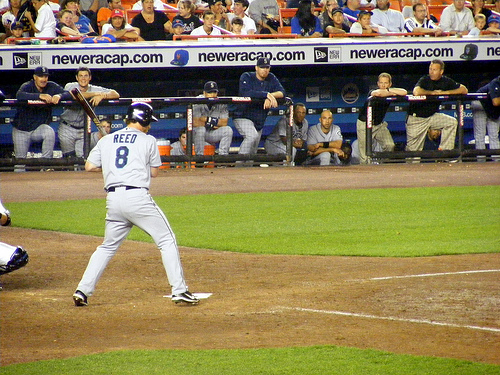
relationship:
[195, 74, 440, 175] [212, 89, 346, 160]
players leaning on fence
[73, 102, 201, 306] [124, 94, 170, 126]
batter wearing helmet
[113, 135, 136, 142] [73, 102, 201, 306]
name on batter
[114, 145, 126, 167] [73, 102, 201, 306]
number on batter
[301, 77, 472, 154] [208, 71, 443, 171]
players in dugout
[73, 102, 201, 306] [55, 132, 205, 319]
batter wearing uniform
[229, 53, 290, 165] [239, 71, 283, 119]
man wearing shirt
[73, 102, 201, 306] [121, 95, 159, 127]
batter wearing helmet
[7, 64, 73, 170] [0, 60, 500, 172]
player in dug out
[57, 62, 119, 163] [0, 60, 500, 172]
player in dug out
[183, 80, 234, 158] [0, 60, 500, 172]
player in dug out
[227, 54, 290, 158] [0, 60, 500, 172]
player in dug out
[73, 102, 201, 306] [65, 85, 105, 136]
batter holding bat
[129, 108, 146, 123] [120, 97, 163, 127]
light shining on helmet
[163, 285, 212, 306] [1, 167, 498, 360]
home plate in dirt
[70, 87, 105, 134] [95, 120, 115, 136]
bat in hand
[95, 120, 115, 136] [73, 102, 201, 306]
hand of batter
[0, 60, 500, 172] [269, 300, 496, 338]
dug out down line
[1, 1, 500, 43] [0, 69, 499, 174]
fans above dugout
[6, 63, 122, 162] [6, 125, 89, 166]
guys with pants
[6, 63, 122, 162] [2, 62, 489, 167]
guys in dug out